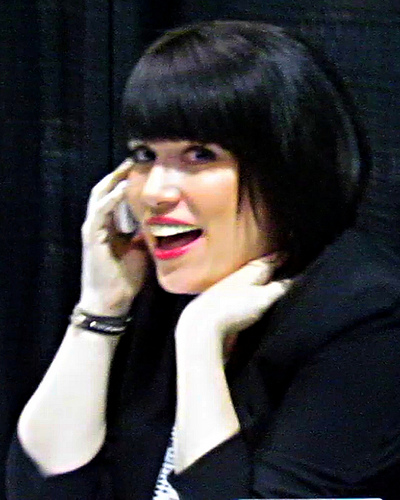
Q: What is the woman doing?
A: Talking on phone.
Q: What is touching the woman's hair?
A: Woman's hand.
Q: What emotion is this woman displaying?
A: Happiness.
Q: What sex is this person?
A: Female.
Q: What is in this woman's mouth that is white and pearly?
A: Teeth.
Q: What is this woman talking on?
A: Phone.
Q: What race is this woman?
A: White.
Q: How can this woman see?
A: Eyes.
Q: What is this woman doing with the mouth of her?
A: Smiling.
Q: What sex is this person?
A: Female.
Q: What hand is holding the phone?
A: Right.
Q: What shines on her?
A: Light.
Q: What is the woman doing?
A: Looking at camera.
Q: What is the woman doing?
A: Talking on phone.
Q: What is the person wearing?
A: Black blazer.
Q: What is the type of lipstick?
A: Pink.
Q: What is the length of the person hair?
A: Short.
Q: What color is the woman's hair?
A: Black.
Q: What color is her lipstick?
A: Red.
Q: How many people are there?
A: One.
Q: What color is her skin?
A: Tan.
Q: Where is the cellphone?
A: In her right hand.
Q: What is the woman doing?
A: Talking on the phone.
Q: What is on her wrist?
A: A bracelet.